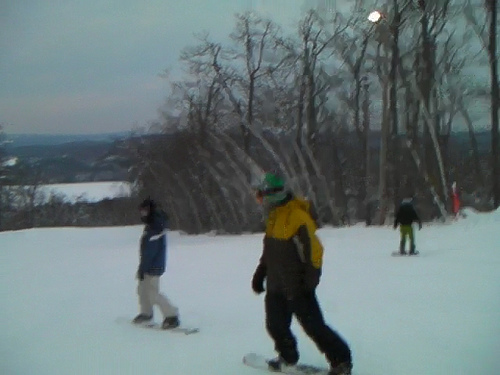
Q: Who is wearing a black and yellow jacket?
A: A skier.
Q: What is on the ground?
A: Snow.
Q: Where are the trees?
A: Behind the snowboarder.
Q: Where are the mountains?
A: Behind the trees.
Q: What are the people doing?
A: Snowboarding.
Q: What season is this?
A: Winter.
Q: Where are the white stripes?
A: On the blue jacket.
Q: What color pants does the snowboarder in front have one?
A: White.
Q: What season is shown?
A: Winter.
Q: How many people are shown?
A: Three.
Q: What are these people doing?
A: Snowboarding.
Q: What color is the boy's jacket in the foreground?
A: Yellow and black.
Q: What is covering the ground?
A: Snow.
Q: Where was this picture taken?
A: A ski slope.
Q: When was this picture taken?
A: Early evening.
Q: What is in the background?
A: Trees.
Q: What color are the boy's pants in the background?
A: Green.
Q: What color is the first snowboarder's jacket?
A: Blue.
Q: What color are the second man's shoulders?
A: Yellow.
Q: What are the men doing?
A: Snowboarding.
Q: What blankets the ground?
A: Snow.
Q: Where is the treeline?
A: Right of the trail.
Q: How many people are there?
A: Three.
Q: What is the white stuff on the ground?
A: Snow.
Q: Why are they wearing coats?
A: It's cold.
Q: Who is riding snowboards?
A: Three people.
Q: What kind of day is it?
A: A snowy day.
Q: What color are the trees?
A: Brown.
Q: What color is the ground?
A: White.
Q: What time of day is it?
A: Evening.